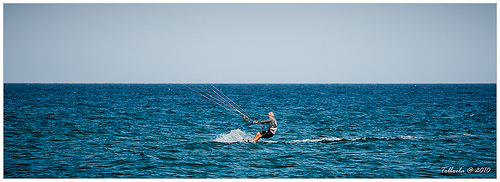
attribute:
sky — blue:
[290, 18, 446, 98]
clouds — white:
[274, 22, 358, 60]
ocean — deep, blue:
[3, 82, 496, 177]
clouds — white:
[347, 18, 407, 40]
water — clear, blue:
[67, 150, 447, 161]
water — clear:
[28, 88, 495, 169]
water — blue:
[2, 82, 496, 180]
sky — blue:
[2, 0, 497, 88]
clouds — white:
[0, 0, 499, 88]